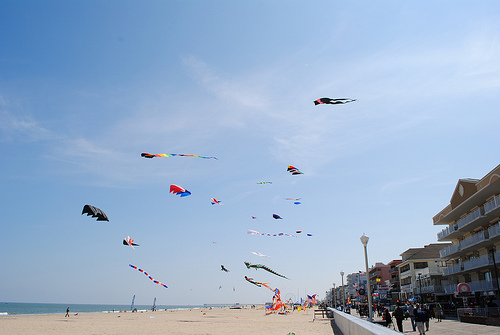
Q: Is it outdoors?
A: Yes, it is outdoors.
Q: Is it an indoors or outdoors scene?
A: It is outdoors.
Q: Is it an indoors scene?
A: No, it is outdoors.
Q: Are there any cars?
A: No, there are no cars.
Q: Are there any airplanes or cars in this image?
A: No, there are no cars or airplanes.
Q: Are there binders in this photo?
A: No, there are no binders.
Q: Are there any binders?
A: No, there are no binders.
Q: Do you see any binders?
A: No, there are no binders.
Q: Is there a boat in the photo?
A: No, there are no boats.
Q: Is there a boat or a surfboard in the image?
A: No, there are no boats or surfboards.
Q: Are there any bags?
A: No, there are no bags.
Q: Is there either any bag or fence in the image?
A: No, there are no bags or fences.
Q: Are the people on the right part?
A: Yes, the people are on the right of the image.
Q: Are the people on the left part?
A: No, the people are on the right of the image.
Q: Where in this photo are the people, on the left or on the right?
A: The people are on the right of the image.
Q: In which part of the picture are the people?
A: The people are on the right of the image.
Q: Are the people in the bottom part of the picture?
A: Yes, the people are in the bottom of the image.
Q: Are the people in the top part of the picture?
A: No, the people are in the bottom of the image.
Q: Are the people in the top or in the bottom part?
A: The people are in the bottom of the image.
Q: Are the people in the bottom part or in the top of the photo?
A: The people are in the bottom of the image.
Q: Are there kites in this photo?
A: Yes, there is a kite.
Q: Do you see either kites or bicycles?
A: Yes, there is a kite.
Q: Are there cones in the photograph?
A: No, there are no cones.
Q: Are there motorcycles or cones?
A: No, there are no cones or motorcycles.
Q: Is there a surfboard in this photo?
A: No, there are no surfboards.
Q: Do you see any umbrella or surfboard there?
A: No, there are no surfboards or umbrellas.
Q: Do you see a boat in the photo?
A: No, there are no boats.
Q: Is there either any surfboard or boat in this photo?
A: No, there are no boats or surfboards.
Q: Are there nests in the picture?
A: No, there are no nests.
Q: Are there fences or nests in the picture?
A: No, there are no nests or fences.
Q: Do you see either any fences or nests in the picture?
A: No, there are no nests or fences.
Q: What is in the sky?
A: The clouds are in the sky.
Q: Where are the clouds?
A: The clouds are in the sky.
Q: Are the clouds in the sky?
A: Yes, the clouds are in the sky.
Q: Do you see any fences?
A: No, there are no fences.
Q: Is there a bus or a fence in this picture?
A: No, there are no fences or buses.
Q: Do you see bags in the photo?
A: No, there are no bags.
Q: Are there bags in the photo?
A: No, there are no bags.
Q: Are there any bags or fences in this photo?
A: No, there are no bags or fences.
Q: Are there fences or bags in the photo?
A: No, there are no bags or fences.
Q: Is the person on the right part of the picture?
A: Yes, the person is on the right of the image.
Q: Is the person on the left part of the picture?
A: No, the person is on the right of the image.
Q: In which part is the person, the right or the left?
A: The person is on the right of the image.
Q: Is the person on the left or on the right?
A: The person is on the right of the image.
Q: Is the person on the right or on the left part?
A: The person is on the right of the image.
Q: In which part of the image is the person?
A: The person is on the right of the image.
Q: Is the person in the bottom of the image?
A: Yes, the person is in the bottom of the image.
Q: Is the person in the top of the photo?
A: No, the person is in the bottom of the image.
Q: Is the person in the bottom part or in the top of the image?
A: The person is in the bottom of the image.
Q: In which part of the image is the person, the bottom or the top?
A: The person is in the bottom of the image.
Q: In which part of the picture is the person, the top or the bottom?
A: The person is in the bottom of the image.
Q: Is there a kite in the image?
A: Yes, there is a kite.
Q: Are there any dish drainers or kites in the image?
A: Yes, there is a kite.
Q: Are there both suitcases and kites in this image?
A: No, there is a kite but no suitcases.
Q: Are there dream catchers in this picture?
A: No, there are no dream catchers.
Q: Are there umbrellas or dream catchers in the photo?
A: No, there are no dream catchers or umbrellas.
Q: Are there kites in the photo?
A: Yes, there is a kite.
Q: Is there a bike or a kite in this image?
A: Yes, there is a kite.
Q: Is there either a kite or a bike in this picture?
A: Yes, there is a kite.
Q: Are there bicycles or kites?
A: Yes, there is a kite.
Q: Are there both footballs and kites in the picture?
A: No, there is a kite but no footballs.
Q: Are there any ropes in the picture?
A: No, there are no ropes.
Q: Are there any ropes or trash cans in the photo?
A: No, there are no ropes or trash cans.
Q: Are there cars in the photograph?
A: No, there are no cars.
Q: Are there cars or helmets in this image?
A: No, there are no cars or helmets.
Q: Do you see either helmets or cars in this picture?
A: No, there are no cars or helmets.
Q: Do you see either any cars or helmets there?
A: No, there are no cars or helmets.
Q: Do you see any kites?
A: Yes, there is a kite.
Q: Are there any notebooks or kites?
A: Yes, there is a kite.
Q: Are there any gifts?
A: No, there are no gifts.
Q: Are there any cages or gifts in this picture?
A: No, there are no gifts or cages.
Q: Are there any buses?
A: No, there are no buses.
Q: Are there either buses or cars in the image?
A: No, there are no buses or cars.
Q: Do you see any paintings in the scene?
A: No, there are no paintings.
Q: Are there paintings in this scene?
A: No, there are no paintings.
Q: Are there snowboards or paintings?
A: No, there are no paintings or snowboards.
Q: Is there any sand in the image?
A: Yes, there is sand.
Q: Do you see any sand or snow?
A: Yes, there is sand.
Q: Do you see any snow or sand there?
A: Yes, there is sand.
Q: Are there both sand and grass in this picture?
A: No, there is sand but no grass.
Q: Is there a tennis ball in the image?
A: No, there are no tennis balls.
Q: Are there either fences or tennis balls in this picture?
A: No, there are no tennis balls or fences.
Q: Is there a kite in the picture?
A: Yes, there is a kite.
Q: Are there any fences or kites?
A: Yes, there is a kite.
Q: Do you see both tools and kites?
A: No, there is a kite but no tools.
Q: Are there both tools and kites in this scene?
A: No, there is a kite but no tools.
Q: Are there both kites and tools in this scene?
A: No, there is a kite but no tools.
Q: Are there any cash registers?
A: No, there are no cash registers.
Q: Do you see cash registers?
A: No, there are no cash registers.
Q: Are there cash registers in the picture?
A: No, there are no cash registers.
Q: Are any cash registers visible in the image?
A: No, there are no cash registers.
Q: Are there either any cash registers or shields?
A: No, there are no cash registers or shields.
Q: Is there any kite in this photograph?
A: Yes, there is a kite.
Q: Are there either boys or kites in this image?
A: Yes, there is a kite.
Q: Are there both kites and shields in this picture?
A: No, there is a kite but no shields.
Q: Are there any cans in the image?
A: No, there are no cans.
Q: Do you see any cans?
A: No, there are no cans.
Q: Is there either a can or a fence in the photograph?
A: No, there are no cans or fences.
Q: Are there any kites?
A: Yes, there is a kite.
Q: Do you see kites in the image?
A: Yes, there is a kite.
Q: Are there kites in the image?
A: Yes, there is a kite.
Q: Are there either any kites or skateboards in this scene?
A: Yes, there is a kite.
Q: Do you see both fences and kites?
A: No, there is a kite but no fences.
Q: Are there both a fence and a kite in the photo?
A: No, there is a kite but no fences.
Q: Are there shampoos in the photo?
A: No, there are no shampoos.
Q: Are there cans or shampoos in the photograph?
A: No, there are no shampoos or cans.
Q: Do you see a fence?
A: No, there are no fences.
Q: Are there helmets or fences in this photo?
A: No, there are no fences or helmets.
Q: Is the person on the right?
A: Yes, the person is on the right of the image.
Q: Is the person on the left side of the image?
A: No, the person is on the right of the image.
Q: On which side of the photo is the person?
A: The person is on the right of the image.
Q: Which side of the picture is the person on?
A: The person is on the right of the image.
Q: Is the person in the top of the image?
A: No, the person is in the bottom of the image.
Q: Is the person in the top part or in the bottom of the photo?
A: The person is in the bottom of the image.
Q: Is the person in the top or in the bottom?
A: The person is in the bottom of the image.